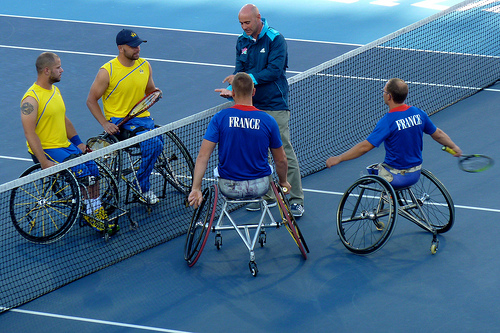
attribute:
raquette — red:
[98, 88, 162, 139]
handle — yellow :
[442, 142, 460, 159]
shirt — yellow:
[101, 55, 150, 120]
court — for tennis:
[0, 12, 499, 328]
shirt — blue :
[365, 100, 442, 177]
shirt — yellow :
[18, 80, 71, 148]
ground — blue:
[258, 281, 480, 316]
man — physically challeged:
[323, 78, 463, 195]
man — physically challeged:
[188, 72, 295, 209]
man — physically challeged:
[90, 23, 170, 208]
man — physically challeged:
[15, 49, 120, 234]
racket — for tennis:
[433, 134, 498, 194]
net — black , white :
[0, 9, 497, 294]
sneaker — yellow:
[75, 194, 115, 241]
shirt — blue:
[368, 103, 440, 168]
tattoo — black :
[15, 92, 45, 117]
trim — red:
[222, 99, 411, 117]